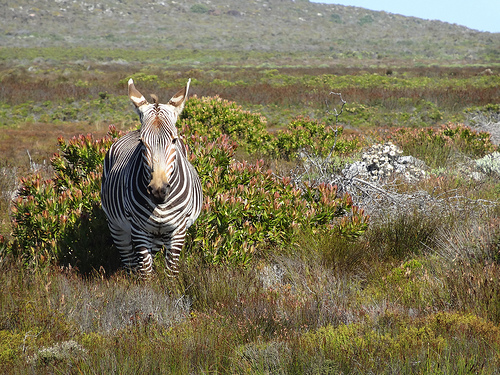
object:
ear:
[127, 78, 148, 109]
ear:
[168, 77, 192, 113]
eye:
[138, 138, 144, 145]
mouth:
[148, 195, 169, 204]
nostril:
[147, 186, 154, 196]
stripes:
[112, 150, 162, 224]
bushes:
[179, 94, 492, 159]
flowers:
[6, 93, 494, 262]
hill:
[8, 1, 498, 74]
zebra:
[100, 77, 205, 284]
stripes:
[167, 197, 192, 230]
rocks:
[345, 142, 428, 186]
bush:
[4, 126, 365, 270]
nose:
[147, 183, 170, 201]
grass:
[0, 255, 499, 374]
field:
[0, 49, 499, 374]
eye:
[172, 137, 178, 144]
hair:
[154, 109, 160, 124]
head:
[126, 77, 191, 205]